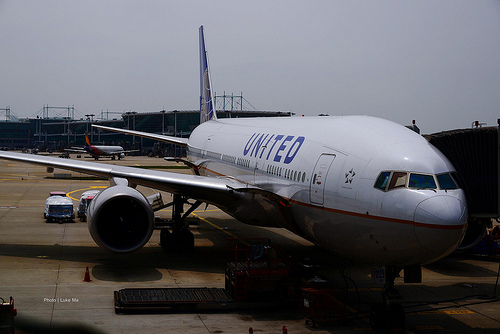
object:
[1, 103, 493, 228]
building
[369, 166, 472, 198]
windshield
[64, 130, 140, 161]
airplane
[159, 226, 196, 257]
wheels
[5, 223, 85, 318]
floor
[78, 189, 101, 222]
truck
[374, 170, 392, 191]
window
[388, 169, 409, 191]
window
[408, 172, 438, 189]
window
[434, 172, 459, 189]
window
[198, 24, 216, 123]
plane tail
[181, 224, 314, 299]
truck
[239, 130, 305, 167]
words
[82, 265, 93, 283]
cone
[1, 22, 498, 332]
plane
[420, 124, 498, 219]
tunnel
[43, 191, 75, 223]
cart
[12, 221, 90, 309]
floor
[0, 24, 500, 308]
aircraft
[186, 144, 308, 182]
windows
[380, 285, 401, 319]
wheels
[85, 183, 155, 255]
engine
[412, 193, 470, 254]
nose